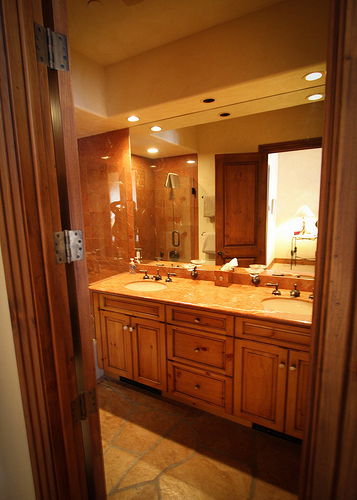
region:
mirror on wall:
[121, 81, 323, 284]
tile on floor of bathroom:
[88, 370, 319, 497]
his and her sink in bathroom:
[83, 259, 315, 328]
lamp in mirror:
[126, 81, 325, 279]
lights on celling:
[62, 1, 325, 124]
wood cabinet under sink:
[85, 249, 313, 442]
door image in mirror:
[123, 82, 325, 285]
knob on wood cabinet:
[85, 286, 167, 392]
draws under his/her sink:
[85, 243, 313, 440]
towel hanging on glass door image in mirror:
[123, 80, 328, 290]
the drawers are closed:
[101, 296, 238, 415]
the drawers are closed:
[167, 289, 249, 440]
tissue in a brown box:
[213, 254, 242, 294]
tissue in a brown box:
[195, 244, 238, 297]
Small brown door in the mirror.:
[213, 152, 268, 266]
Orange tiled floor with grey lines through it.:
[98, 380, 299, 499]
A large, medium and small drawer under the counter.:
[164, 303, 234, 416]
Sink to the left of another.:
[123, 279, 167, 293]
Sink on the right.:
[260, 294, 315, 317]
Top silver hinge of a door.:
[52, 229, 84, 263]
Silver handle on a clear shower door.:
[173, 230, 180, 246]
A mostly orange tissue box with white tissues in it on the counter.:
[213, 256, 237, 285]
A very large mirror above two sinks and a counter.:
[125, 81, 328, 282]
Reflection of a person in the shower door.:
[108, 197, 137, 243]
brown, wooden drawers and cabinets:
[89, 296, 294, 422]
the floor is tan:
[135, 421, 226, 486]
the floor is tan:
[98, 403, 181, 476]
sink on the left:
[95, 234, 178, 329]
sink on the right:
[251, 273, 302, 329]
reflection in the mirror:
[158, 177, 308, 256]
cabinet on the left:
[95, 305, 168, 394]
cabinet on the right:
[224, 318, 307, 450]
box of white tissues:
[208, 255, 248, 299]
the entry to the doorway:
[54, 185, 321, 488]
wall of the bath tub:
[82, 180, 134, 282]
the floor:
[101, 391, 219, 497]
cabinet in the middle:
[158, 296, 241, 438]